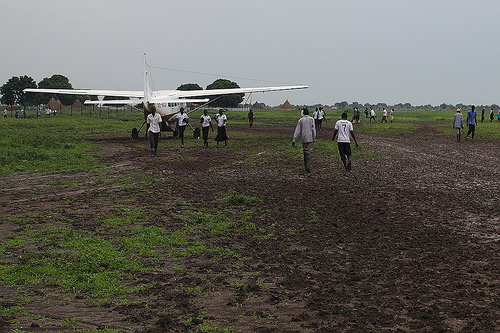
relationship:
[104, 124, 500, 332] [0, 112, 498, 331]
mud in field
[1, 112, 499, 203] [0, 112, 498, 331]
grass in field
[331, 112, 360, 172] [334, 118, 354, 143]
man has shirt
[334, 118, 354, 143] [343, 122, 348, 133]
shirt has a 7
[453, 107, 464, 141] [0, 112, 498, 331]
person are in a field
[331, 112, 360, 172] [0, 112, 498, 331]
man in field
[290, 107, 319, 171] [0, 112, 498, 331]
man in field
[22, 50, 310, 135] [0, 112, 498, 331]
plane in field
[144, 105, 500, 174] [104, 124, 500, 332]
people are on mud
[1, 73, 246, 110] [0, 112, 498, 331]
trees are by field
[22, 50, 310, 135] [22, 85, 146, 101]
plane has wing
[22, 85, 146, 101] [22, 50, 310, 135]
wing on plane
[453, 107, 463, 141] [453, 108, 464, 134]
person wearing outfit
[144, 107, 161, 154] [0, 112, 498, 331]
person in field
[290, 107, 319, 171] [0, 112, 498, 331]
person in field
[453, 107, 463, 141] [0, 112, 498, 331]
person in field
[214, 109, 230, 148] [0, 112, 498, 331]
girls in field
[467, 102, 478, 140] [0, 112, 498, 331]
person in field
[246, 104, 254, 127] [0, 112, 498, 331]
person in field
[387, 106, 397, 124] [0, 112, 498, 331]
person in field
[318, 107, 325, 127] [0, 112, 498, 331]
person in field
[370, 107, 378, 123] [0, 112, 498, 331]
person in field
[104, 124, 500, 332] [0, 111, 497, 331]
mud on field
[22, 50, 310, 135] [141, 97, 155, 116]
plane has propeller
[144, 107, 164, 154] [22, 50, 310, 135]
person are walking from plane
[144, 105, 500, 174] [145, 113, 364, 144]
people have shirts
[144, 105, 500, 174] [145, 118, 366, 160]
people have pants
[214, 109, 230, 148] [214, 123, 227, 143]
girls has skirt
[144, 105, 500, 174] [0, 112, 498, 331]
people are on field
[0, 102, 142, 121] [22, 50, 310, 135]
fence near plane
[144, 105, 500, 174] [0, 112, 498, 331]
people are in field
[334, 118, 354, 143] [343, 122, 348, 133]
shirt has 7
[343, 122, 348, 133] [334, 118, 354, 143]
7 on shirt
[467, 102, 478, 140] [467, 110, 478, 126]
man has shirt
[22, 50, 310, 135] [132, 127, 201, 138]
plane has wheels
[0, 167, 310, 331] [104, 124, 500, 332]
patches are on dirt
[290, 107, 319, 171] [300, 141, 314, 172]
man has pants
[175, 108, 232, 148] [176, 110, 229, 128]
girls have shirts